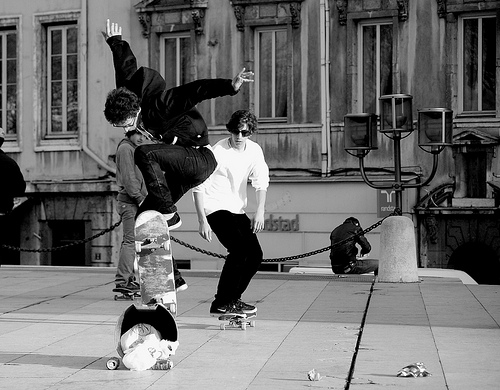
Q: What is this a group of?
A: Skateboarders.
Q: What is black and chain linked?
A: Rope.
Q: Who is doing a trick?
A: The teen.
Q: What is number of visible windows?
A: Six.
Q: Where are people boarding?
A: Sidewalk.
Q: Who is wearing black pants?
A: The guy.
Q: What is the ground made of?
A: Concrete.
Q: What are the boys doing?
A: Riding skateboards.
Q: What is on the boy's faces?
A: Glasses.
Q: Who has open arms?
A: The man.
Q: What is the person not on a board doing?
A: Sitting.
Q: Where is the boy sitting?
A: On the sidewalk.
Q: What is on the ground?
A: Trash.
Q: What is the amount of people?
A: Four.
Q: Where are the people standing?
A: On a platform.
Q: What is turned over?
A: Garbage pail.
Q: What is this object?
A: Chain.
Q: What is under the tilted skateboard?
A: Trash can.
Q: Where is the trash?
A: On the ground.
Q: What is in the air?
A: Skateboarders arms.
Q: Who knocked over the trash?
A: One of the skateboarders.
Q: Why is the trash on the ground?
A: Hit by the skateboard.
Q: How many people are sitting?
A: One.